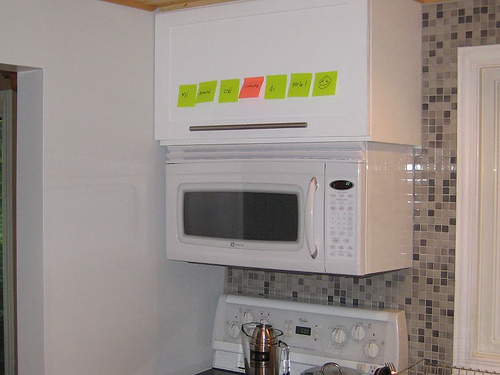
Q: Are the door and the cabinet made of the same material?
A: No, the door is made of glass and the cabinet is made of wood.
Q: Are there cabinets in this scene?
A: Yes, there is a cabinet.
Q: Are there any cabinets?
A: Yes, there is a cabinet.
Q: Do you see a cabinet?
A: Yes, there is a cabinet.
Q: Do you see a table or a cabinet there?
A: Yes, there is a cabinet.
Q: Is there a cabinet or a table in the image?
A: Yes, there is a cabinet.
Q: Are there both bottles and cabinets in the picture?
A: No, there is a cabinet but no bottles.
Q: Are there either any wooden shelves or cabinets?
A: Yes, there is a wood cabinet.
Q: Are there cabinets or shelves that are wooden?
A: Yes, the cabinet is wooden.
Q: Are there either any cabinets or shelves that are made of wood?
A: Yes, the cabinet is made of wood.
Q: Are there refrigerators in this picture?
A: No, there are no refrigerators.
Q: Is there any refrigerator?
A: No, there are no refrigerators.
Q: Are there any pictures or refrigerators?
A: No, there are no refrigerators or pictures.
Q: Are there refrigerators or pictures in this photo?
A: No, there are no refrigerators or pictures.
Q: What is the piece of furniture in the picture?
A: The piece of furniture is a cabinet.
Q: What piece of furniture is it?
A: The piece of furniture is a cabinet.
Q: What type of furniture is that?
A: That is a cabinet.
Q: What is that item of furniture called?
A: That is a cabinet.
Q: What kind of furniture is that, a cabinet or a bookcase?
A: That is a cabinet.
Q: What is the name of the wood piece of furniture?
A: The piece of furniture is a cabinet.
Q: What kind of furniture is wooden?
A: The furniture is a cabinet.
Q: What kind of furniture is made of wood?
A: The furniture is a cabinet.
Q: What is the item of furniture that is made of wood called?
A: The piece of furniture is a cabinet.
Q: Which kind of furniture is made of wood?
A: The furniture is a cabinet.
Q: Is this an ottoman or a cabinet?
A: This is a cabinet.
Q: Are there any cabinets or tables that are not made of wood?
A: No, there is a cabinet but it is made of wood.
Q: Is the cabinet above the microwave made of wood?
A: Yes, the cabinet is made of wood.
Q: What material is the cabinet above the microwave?
A: The cabinet is made of wood.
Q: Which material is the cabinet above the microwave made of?
A: The cabinet is made of wood.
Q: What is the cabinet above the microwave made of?
A: The cabinet is made of wood.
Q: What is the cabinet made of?
A: The cabinet is made of wood.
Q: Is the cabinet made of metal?
A: No, the cabinet is made of wood.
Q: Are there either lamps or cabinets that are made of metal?
A: No, there is a cabinet but it is made of wood.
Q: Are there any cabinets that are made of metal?
A: No, there is a cabinet but it is made of wood.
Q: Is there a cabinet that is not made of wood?
A: No, there is a cabinet but it is made of wood.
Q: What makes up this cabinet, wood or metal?
A: The cabinet is made of wood.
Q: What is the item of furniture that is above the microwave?
A: The piece of furniture is a cabinet.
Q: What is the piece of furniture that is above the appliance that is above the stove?
A: The piece of furniture is a cabinet.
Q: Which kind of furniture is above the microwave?
A: The piece of furniture is a cabinet.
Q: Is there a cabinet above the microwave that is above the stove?
A: Yes, there is a cabinet above the microwave.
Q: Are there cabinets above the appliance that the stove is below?
A: Yes, there is a cabinet above the microwave.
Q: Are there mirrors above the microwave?
A: No, there is a cabinet above the microwave.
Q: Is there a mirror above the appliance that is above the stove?
A: No, there is a cabinet above the microwave.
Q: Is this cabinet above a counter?
A: No, the cabinet is above the microwave.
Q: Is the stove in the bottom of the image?
A: Yes, the stove is in the bottom of the image.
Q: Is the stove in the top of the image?
A: No, the stove is in the bottom of the image.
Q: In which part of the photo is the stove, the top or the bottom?
A: The stove is in the bottom of the image.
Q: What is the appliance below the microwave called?
A: The appliance is a stove.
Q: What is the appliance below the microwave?
A: The appliance is a stove.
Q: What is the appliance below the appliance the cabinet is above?
A: The appliance is a stove.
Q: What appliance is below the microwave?
A: The appliance is a stove.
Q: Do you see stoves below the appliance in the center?
A: Yes, there is a stove below the microwave.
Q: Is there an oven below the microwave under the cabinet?
A: No, there is a stove below the microwave.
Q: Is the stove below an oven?
A: No, the stove is below a microwave.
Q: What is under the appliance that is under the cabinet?
A: The stove is under the microwave.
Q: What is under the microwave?
A: The stove is under the microwave.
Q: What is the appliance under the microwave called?
A: The appliance is a stove.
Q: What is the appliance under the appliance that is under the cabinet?
A: The appliance is a stove.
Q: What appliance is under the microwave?
A: The appliance is a stove.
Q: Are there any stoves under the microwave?
A: Yes, there is a stove under the microwave.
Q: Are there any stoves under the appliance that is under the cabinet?
A: Yes, there is a stove under the microwave.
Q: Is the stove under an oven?
A: No, the stove is under the microwave.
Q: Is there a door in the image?
A: Yes, there is a door.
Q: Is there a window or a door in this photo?
A: Yes, there is a door.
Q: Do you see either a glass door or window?
A: Yes, there is a glass door.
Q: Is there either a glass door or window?
A: Yes, there is a glass door.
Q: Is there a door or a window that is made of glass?
A: Yes, the door is made of glass.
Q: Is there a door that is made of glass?
A: Yes, there is a door that is made of glass.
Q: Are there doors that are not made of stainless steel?
A: Yes, there is a door that is made of glass.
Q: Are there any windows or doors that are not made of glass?
A: No, there is a door but it is made of glass.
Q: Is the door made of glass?
A: Yes, the door is made of glass.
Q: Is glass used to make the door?
A: Yes, the door is made of glass.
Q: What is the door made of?
A: The door is made of glass.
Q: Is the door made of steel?
A: No, the door is made of glass.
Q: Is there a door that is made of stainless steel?
A: No, there is a door but it is made of glass.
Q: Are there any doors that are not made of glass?
A: No, there is a door but it is made of glass.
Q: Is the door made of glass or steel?
A: The door is made of glass.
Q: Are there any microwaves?
A: Yes, there is a microwave.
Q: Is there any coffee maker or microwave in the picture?
A: Yes, there is a microwave.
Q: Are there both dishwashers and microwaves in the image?
A: No, there is a microwave but no dishwashers.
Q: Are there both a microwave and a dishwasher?
A: No, there is a microwave but no dishwashers.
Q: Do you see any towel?
A: No, there are no towels.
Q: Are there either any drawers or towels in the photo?
A: No, there are no towels or drawers.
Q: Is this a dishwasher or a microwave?
A: This is a microwave.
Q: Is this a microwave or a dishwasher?
A: This is a microwave.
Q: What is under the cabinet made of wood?
A: The microwave is under the cabinet.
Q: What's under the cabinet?
A: The microwave is under the cabinet.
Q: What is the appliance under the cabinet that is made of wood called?
A: The appliance is a microwave.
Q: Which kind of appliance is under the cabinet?
A: The appliance is a microwave.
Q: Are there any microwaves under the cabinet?
A: Yes, there is a microwave under the cabinet.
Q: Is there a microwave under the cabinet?
A: Yes, there is a microwave under the cabinet.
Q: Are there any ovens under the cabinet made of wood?
A: No, there is a microwave under the cabinet.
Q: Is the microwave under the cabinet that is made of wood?
A: Yes, the microwave is under the cabinet.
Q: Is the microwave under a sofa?
A: No, the microwave is under the cabinet.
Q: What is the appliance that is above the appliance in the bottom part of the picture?
A: The appliance is a microwave.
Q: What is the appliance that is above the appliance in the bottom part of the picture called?
A: The appliance is a microwave.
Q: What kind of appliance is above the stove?
A: The appliance is a microwave.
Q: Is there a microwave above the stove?
A: Yes, there is a microwave above the stove.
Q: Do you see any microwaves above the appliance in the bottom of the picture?
A: Yes, there is a microwave above the stove.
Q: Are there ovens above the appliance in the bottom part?
A: No, there is a microwave above the stove.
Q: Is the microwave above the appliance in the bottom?
A: Yes, the microwave is above the stove.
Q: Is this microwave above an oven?
A: No, the microwave is above the stove.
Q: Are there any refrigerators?
A: No, there are no refrigerators.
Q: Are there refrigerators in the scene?
A: No, there are no refrigerators.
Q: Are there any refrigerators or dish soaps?
A: No, there are no refrigerators or dish soaps.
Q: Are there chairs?
A: No, there are no chairs.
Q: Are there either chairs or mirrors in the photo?
A: No, there are no chairs or mirrors.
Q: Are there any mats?
A: No, there are no mats.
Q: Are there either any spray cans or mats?
A: No, there are no mats or spray cans.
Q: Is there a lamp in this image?
A: No, there are no lamps.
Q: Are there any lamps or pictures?
A: No, there are no lamps or pictures.